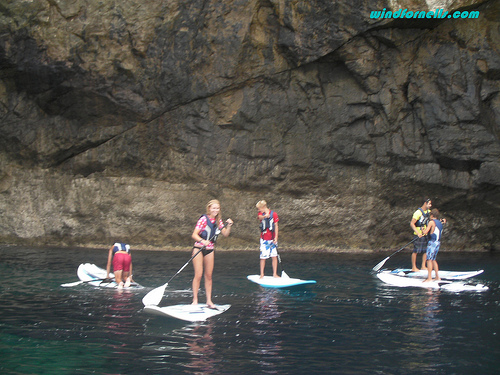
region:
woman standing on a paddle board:
[114, 201, 244, 333]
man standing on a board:
[234, 190, 303, 308]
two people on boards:
[358, 162, 498, 309]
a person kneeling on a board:
[28, 222, 147, 317]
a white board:
[240, 256, 318, 300]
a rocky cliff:
[91, 20, 392, 180]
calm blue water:
[311, 303, 399, 357]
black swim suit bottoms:
[189, 235, 221, 258]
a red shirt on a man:
[254, 209, 289, 242]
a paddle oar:
[130, 238, 242, 315]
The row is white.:
[135, 277, 175, 307]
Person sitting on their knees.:
[103, 236, 140, 291]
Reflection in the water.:
[161, 329, 227, 374]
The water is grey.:
[294, 312, 396, 362]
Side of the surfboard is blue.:
[264, 274, 323, 292]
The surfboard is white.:
[164, 298, 196, 321]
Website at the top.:
[358, 0, 480, 27]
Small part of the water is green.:
[5, 335, 114, 372]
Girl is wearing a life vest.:
[187, 215, 227, 246]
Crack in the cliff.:
[41, 2, 487, 172]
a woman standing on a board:
[136, 182, 251, 369]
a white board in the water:
[139, 294, 264, 320]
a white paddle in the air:
[138, 201, 238, 333]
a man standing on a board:
[234, 182, 311, 322]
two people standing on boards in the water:
[352, 168, 484, 307]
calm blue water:
[301, 301, 458, 348]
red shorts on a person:
[102, 247, 137, 274]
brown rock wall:
[32, 10, 288, 167]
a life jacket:
[248, 205, 287, 238]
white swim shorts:
[245, 233, 299, 265]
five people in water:
[56, 171, 498, 355]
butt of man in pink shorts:
[102, 231, 140, 295]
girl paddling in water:
[134, 176, 239, 349]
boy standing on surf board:
[242, 186, 314, 321]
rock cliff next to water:
[12, 17, 102, 258]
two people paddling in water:
[353, 180, 493, 313]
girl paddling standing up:
[138, 186, 245, 336]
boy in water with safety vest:
[241, 180, 324, 318]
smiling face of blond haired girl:
[193, 191, 237, 229]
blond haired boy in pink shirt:
[246, 193, 294, 250]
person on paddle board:
[98, 237, 135, 289]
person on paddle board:
[191, 193, 229, 308]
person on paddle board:
[251, 196, 295, 267]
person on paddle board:
[422, 210, 445, 268]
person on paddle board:
[403, 199, 424, 254]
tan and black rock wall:
[15, 7, 360, 192]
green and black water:
[10, 256, 57, 355]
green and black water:
[253, 297, 486, 363]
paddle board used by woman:
[158, 306, 235, 321]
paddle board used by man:
[248, 273, 321, 302]